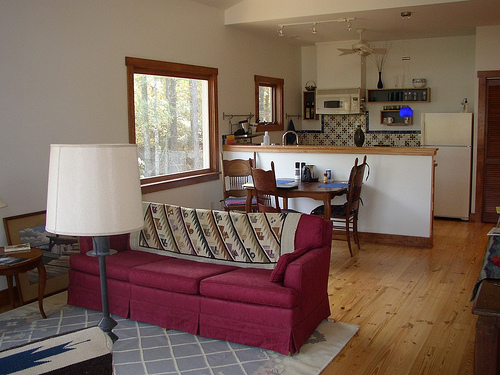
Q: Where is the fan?
A: On the ceiling.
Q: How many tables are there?
A: 2.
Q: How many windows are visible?
A: 2.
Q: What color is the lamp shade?
A: White.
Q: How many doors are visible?
A: 1.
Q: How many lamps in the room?
A: 1.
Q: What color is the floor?
A: Brown.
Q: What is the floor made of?
A: Wood.